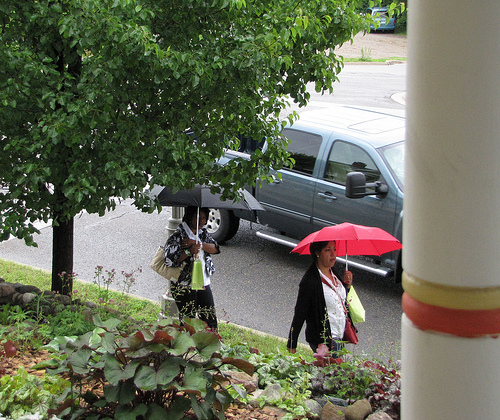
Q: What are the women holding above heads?
A: Umbrellas.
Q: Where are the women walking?
A: On sidewalk.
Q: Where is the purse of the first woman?
A: Across chest and shoulders.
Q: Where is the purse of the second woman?
A: On right shoulder.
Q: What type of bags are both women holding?
A: Green shopping bags.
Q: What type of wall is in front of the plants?
A: Stone wall.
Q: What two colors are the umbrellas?
A: Red and black.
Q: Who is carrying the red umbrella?
A: First woman.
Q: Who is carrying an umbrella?
A: The woman.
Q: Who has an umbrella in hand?
A: The woman walking.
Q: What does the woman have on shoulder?
A: Purse.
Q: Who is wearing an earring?
A: The woman.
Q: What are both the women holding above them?
A: Umbrellas.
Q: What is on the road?
A: A gray truck.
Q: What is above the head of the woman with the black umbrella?
A: A tree.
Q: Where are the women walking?
A: The sidewalk.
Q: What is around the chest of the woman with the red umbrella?
A: A purse.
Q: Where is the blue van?
A: In a parking lot.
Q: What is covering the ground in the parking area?
A: Gravel.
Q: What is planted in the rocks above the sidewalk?
A: Plants and flowers.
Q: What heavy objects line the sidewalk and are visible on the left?
A: Rocks.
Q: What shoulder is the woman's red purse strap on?
A: Her right shoulder.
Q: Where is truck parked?
A: Down road.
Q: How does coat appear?
A: Black in color.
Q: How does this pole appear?
A: Yellow and red stripes.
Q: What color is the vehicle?
A: Blue.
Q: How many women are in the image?
A: 2.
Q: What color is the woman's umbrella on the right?
A: Red.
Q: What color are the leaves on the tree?
A: Green.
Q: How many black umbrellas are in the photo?
A: 1.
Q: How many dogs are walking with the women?
A: 0.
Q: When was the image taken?
A: Daytime.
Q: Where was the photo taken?
A: On the sidewalk.